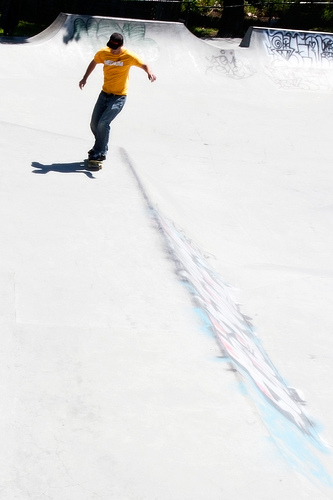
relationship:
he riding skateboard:
[78, 29, 158, 162] [87, 158, 103, 170]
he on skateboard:
[78, 29, 158, 162] [81, 158, 107, 169]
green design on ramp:
[69, 15, 159, 68] [45, 10, 224, 77]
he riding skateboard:
[78, 29, 158, 162] [72, 142, 104, 170]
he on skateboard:
[78, 29, 158, 162] [82, 156, 101, 171]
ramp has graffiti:
[22, 11, 331, 494] [261, 28, 332, 68]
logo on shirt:
[101, 57, 126, 68] [92, 46, 141, 92]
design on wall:
[269, 31, 328, 64] [250, 33, 332, 92]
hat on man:
[102, 30, 126, 48] [75, 24, 159, 99]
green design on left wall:
[64, 15, 159, 61] [4, 22, 193, 273]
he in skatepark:
[78, 29, 158, 162] [65, 7, 331, 132]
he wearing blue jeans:
[78, 32, 155, 159] [89, 92, 124, 153]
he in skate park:
[78, 29, 158, 162] [9, 17, 330, 357]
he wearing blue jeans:
[78, 29, 158, 162] [89, 88, 126, 160]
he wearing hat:
[78, 29, 158, 162] [105, 32, 124, 49]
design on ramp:
[266, 31, 332, 65] [247, 25, 332, 116]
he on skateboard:
[78, 29, 158, 162] [87, 157, 101, 168]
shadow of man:
[26, 152, 103, 186] [64, 24, 153, 174]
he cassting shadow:
[78, 29, 158, 162] [20, 153, 100, 177]